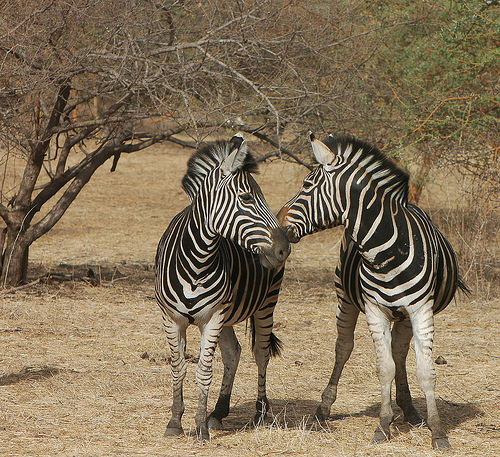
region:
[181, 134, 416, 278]
two zebras playing in the field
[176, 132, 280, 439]
black and white striped zebra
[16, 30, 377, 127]
tree has lost all leaves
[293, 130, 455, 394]
zebra standing near the trees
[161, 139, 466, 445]
zebras standing on the barren ground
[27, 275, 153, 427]
brown dry ground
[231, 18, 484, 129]
green trees in the distance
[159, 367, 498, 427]
shadows on the ground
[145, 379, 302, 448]
zebra hooves on the ground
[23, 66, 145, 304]
tree without any leaves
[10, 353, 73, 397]
spot on brown dirt on ground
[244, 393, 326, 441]
tiny amount of brown grass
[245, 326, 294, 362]
busy tail on zebra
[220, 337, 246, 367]
fat knuckle on feet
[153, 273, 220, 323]
black stripe around zebra's body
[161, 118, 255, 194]
comb on zebra's back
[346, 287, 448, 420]
zebra's white legs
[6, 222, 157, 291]
shadow under wide tree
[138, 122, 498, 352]
pair of zebra's playing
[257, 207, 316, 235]
brown spot on zebra's nose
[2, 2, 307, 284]
a tree next to two zebras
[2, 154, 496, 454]
dry savannah grass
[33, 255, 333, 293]
the shadow of a tree on the ground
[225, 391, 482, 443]
the shadows of two zebras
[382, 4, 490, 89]
green leaves in the background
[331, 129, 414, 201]
a black and white zebra mane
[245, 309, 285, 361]
the black tail of a zebra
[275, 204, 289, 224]
a brown patch on a zebra's nose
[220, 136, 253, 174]
a zebra ear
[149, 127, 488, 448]
two zebras nosing each other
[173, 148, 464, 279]
two zebras together in photo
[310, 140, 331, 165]
horns on the zebra's head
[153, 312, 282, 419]
animal has four legs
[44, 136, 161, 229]
tree limb is bent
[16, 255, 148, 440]
grass is burnt on surface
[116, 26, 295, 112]
twigs hanging over tree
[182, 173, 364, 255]
two zebras close to each other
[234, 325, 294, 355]
bushy tail on zebra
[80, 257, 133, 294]
dark objects in the grass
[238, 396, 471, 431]
shadows casting on ground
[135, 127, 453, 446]
the two zebras standing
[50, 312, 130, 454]
the brown grass on the ground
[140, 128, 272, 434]
the zebra on the left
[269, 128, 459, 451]
the zebra on the right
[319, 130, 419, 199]
the mane on the right zebra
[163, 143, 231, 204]
the mane on the zebra on the left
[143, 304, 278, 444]
the legs on the zebra on the left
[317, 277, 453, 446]
the legs on the zebra on the right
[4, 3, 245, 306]
the tall brown tree on the left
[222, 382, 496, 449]
the shadow on the ground from the zebras